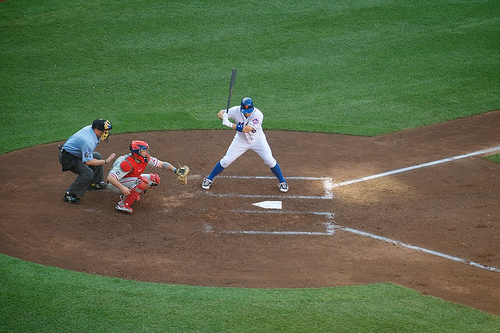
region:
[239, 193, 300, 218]
home base in a baseball game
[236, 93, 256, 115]
blue protective helmet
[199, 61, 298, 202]
pro ball player at bat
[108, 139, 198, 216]
catcher with glove on hand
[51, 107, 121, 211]
referee watching the play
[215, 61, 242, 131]
hands holding baseball bat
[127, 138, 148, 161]
catcher's face mask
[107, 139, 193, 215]
catcher wearing red protective padding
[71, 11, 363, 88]
grass on the stadium playing field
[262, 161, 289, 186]
a blue sock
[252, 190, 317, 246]
Home plate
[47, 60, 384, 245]
A baseball game.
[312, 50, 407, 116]
baseball field grass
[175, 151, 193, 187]
a catcher's mitt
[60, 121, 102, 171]
An umpire in a blue shirt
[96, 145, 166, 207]
a baseball catcher with red protective gear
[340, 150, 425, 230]
Sun reflecting on the ground.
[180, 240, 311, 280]
A baseball field dirt ground.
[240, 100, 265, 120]
A blue baseball helmet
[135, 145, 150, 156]
A catcher's guard mask.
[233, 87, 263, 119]
man wears blue helmet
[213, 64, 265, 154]
man wears white shirt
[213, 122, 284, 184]
man wears white pants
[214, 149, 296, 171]
man wears blue socks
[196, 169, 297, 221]
man wears blue shoes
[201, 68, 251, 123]
man is holding bat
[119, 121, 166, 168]
catcher wears red helmet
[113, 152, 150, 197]
catcher wears red chest guard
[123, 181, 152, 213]
catcher wears red shin guard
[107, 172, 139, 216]
catcher wears grey uniform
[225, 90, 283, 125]
He is wearing a helmet.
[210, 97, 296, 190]
He is wearing a white jersey.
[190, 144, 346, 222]
He is wearing blue socks.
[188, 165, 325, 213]
He is wearing blue shoes.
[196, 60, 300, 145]
The batter is swinging the bat.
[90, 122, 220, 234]
The catcher is wearing red.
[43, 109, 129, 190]
The umpire is watching.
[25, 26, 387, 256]
They are playing baseball.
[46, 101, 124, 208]
The ump is wearing a blue shirt.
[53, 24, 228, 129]
The grass is lush.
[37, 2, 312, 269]
three poeple playing baseball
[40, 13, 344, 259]
three people on a baseball field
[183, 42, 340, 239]
a man playing baseball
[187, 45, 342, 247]
a man holding a bat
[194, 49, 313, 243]
a man up to bat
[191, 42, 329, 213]
a baseball player batting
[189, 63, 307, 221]
a baseball player with blue helmet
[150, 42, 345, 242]
a baseball player with helmet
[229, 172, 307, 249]
home base on field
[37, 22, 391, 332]
a baseball field